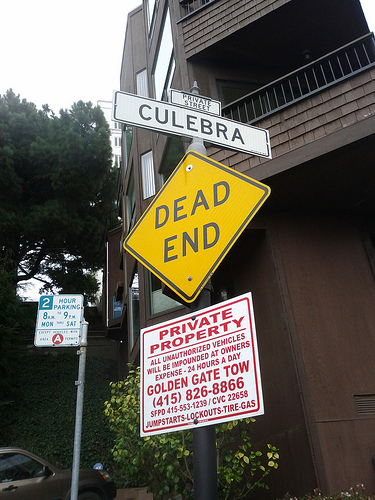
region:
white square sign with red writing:
[129, 289, 276, 443]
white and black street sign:
[92, 60, 283, 171]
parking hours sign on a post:
[22, 282, 105, 494]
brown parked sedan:
[3, 438, 124, 499]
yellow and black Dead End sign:
[84, 125, 284, 301]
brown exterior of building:
[68, 6, 372, 186]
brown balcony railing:
[196, 27, 373, 108]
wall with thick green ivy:
[9, 355, 71, 446]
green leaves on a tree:
[4, 73, 111, 286]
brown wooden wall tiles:
[279, 84, 363, 154]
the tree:
[10, 133, 152, 337]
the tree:
[18, 44, 149, 241]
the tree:
[8, 104, 110, 267]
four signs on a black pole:
[111, 83, 277, 498]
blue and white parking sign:
[37, 293, 84, 343]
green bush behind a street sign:
[103, 291, 280, 498]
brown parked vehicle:
[1, 441, 121, 498]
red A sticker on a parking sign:
[51, 334, 64, 344]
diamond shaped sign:
[106, 147, 278, 302]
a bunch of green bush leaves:
[222, 428, 287, 497]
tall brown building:
[113, 2, 369, 491]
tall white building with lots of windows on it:
[92, 92, 122, 170]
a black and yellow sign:
[118, 154, 258, 294]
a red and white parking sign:
[144, 322, 254, 429]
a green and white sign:
[22, 285, 89, 353]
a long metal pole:
[74, 350, 87, 498]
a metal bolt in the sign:
[180, 154, 204, 178]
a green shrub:
[118, 392, 144, 462]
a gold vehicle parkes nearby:
[4, 445, 59, 499]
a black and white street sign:
[117, 90, 276, 162]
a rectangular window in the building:
[137, 144, 159, 200]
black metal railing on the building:
[276, 72, 312, 98]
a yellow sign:
[85, 104, 306, 356]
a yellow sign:
[99, 64, 255, 301]